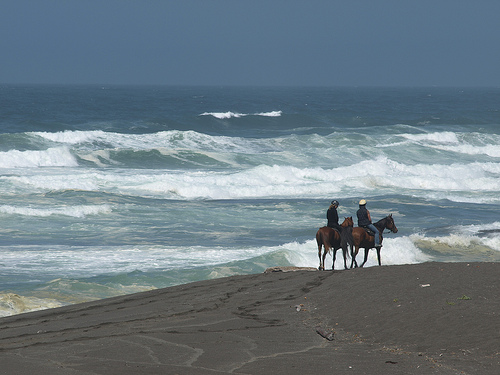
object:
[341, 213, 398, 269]
horse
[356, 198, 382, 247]
person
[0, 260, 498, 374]
beach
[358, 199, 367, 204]
helmet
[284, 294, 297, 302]
hoof print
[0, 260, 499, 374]
sand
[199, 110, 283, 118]
wave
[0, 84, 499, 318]
ocean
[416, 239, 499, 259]
foam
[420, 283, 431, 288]
stick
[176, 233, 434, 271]
wave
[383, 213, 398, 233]
head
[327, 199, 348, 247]
rider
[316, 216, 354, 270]
horse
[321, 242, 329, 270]
horse's leg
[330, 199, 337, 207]
helmet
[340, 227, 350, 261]
tail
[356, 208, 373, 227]
shirt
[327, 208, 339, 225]
shirt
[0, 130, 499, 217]
wave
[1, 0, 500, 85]
sky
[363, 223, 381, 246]
jeans